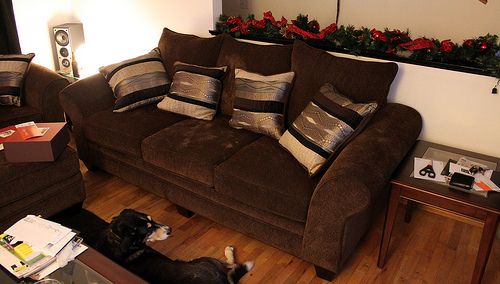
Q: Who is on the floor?
A: The dog.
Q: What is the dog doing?
A: Lounging.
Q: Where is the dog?
A: In a living room.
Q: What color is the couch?
A: Brown.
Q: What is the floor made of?
A: Wood.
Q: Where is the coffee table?
A: In front of the couch.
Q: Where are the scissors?
A: On the side table.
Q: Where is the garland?
A: Behind the couch.